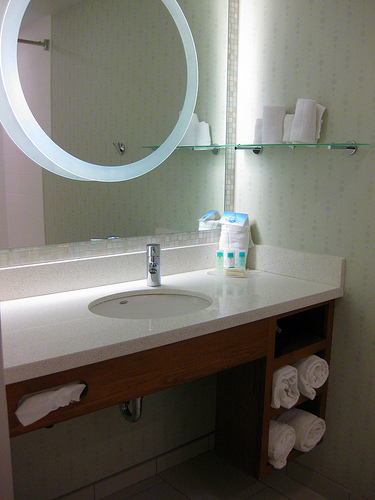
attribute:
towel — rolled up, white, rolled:
[271, 366, 303, 410]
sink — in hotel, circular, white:
[88, 288, 214, 321]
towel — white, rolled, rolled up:
[292, 353, 329, 400]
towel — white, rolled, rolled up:
[268, 421, 296, 470]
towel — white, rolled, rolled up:
[276, 407, 325, 452]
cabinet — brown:
[6, 301, 334, 480]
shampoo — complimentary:
[215, 251, 224, 269]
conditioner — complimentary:
[225, 249, 236, 269]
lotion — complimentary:
[235, 246, 248, 267]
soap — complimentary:
[223, 268, 247, 279]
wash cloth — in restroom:
[253, 118, 263, 147]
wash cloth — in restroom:
[283, 112, 295, 143]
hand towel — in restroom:
[262, 105, 288, 145]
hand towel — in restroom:
[287, 98, 325, 149]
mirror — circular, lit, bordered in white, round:
[1, 1, 200, 184]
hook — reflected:
[113, 142, 127, 154]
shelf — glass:
[231, 142, 367, 148]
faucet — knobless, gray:
[146, 243, 164, 289]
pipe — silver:
[120, 396, 145, 425]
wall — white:
[234, 2, 374, 500]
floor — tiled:
[104, 448, 327, 500]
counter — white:
[0, 240, 346, 385]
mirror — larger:
[2, 2, 237, 269]